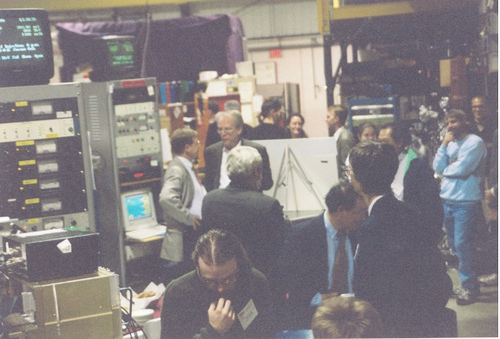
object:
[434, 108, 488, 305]
person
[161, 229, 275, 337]
man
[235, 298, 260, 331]
tag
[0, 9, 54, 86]
tv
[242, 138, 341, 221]
board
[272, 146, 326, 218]
stand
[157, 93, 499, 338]
men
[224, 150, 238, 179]
ties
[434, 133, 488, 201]
sweater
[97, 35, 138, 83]
screen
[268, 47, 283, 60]
sign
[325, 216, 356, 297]
shirt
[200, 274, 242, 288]
glasses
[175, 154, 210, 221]
shirt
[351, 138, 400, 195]
hair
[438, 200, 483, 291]
jeans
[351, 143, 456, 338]
jacket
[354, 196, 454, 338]
person